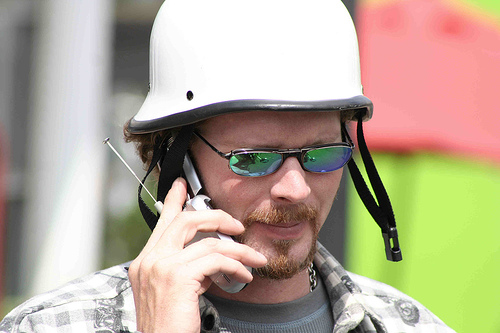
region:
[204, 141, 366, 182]
spects of the person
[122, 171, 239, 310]
hand of the person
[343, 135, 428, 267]
side strip of the cap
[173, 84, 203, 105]
a black dot on cap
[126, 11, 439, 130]
a white helmet wearing by person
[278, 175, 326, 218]
nose of the person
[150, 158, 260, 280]
a cellular phone of person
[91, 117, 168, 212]
antenna of the phone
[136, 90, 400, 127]
a black line in cat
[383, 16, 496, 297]
a wall in the back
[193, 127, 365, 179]
Black rimmed sun glasses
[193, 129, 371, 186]
Black sunglasses with reflective lenses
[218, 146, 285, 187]
Reflective lense on sun glasses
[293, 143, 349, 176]
Reflective lense on sun glasses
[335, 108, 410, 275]
Black fabric strap on a helmet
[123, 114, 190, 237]
Black fabric strap on a helmet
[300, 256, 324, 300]
Small part of silver shain around neck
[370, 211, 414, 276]
Plastic part of a black strap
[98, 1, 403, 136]
Black and white helmet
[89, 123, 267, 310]
Man holding a silver cell phone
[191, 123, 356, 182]
A pair of sunglasses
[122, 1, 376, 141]
A helmet is white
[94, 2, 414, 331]
Man holding a cell phone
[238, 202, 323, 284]
Facial hair on man's face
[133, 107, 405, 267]
Black straps on a helmet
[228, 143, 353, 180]
Reflections on the sunglass lenses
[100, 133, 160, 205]
Antenna of a cell phone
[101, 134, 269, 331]
A cell phone in a hand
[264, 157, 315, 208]
Nose on man's face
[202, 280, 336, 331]
The shirt is gray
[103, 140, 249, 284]
A person talking on the mobile phone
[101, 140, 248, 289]
Silver color mobile phone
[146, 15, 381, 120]
A person wearing white color helmet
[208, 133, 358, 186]
A person wearing goggle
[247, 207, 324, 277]
A person mustache with beard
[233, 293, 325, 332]
A person wearing grey color round neck t-shirt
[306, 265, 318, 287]
A person wearing silver color chain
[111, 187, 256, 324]
A person holding the mobile phone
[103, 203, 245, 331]
Hand of the person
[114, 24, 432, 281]
Head of the person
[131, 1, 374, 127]
white plastic construction hat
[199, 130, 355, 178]
sun glasses on face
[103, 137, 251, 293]
cell phone in hand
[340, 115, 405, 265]
black strap on hard hat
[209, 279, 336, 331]
grey cotton tee shirt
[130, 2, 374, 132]
hard hat on head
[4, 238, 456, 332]
grey plaid cotton shirt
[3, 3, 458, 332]
man wearing hard hat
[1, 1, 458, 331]
man wearing sun glasses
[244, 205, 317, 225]
brown mustache on face